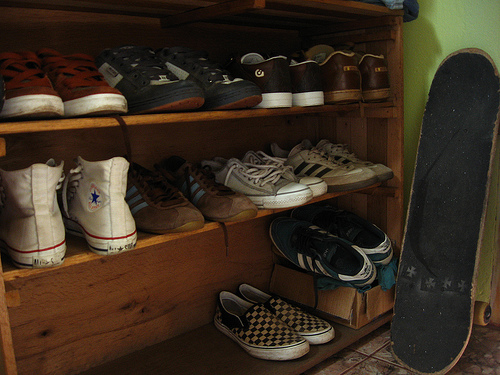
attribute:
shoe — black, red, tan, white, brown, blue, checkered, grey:
[98, 45, 205, 115]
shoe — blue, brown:
[269, 217, 380, 290]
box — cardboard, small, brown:
[270, 263, 396, 327]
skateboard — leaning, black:
[392, 47, 497, 374]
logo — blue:
[91, 191, 101, 206]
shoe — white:
[63, 158, 139, 254]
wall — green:
[403, 2, 497, 324]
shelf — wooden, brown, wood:
[1, 0, 405, 374]